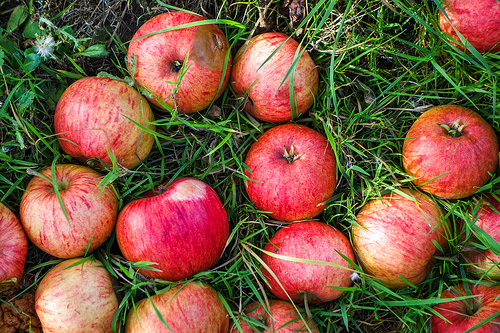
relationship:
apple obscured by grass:
[240, 121, 340, 223] [12, 45, 419, 296]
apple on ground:
[240, 121, 340, 223] [5, 3, 499, 330]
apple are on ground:
[240, 121, 340, 223] [5, 3, 499, 330]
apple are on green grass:
[240, 121, 340, 223] [0, 0, 499, 333]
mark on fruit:
[185, 20, 229, 70] [130, 7, 255, 90]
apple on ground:
[240, 121, 340, 223] [67, 14, 440, 320]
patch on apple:
[166, 177, 209, 203] [114, 176, 235, 283]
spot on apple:
[189, 24, 229, 82] [142, 33, 272, 120]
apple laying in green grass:
[243, 119, 344, 230] [0, 0, 499, 333]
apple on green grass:
[240, 121, 340, 223] [0, 0, 499, 331]